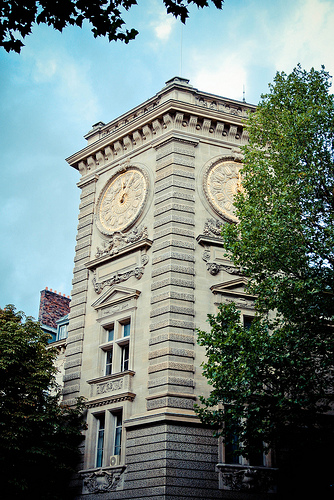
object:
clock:
[94, 157, 154, 237]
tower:
[124, 72, 221, 500]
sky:
[276, 4, 333, 63]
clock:
[198, 156, 276, 228]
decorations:
[89, 228, 150, 263]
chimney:
[40, 284, 72, 324]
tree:
[208, 55, 334, 490]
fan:
[109, 454, 120, 466]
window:
[110, 408, 122, 462]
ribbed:
[167, 205, 195, 416]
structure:
[136, 137, 206, 464]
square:
[56, 314, 70, 340]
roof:
[66, 85, 174, 161]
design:
[79, 467, 122, 496]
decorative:
[94, 231, 149, 253]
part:
[145, 332, 198, 410]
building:
[130, 404, 205, 500]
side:
[116, 344, 160, 420]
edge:
[158, 433, 173, 500]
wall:
[169, 331, 215, 500]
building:
[215, 98, 296, 486]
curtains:
[95, 417, 103, 469]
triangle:
[91, 283, 141, 310]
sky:
[0, 20, 79, 79]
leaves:
[200, 397, 228, 431]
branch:
[211, 320, 254, 362]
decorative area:
[84, 233, 152, 293]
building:
[64, 118, 133, 497]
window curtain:
[115, 414, 122, 456]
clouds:
[182, 35, 252, 79]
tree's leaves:
[0, 0, 110, 55]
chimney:
[35, 286, 70, 329]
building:
[34, 323, 67, 426]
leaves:
[194, 372, 246, 417]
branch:
[256, 318, 331, 354]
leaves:
[32, 382, 53, 404]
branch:
[1, 330, 35, 353]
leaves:
[27, 320, 34, 329]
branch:
[0, 355, 26, 376]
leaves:
[220, 307, 238, 328]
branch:
[304, 390, 334, 419]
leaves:
[60, 411, 73, 431]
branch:
[0, 410, 18, 453]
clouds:
[30, 50, 101, 95]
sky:
[2, 203, 61, 284]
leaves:
[303, 302, 317, 329]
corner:
[145, 69, 196, 499]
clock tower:
[59, 74, 313, 498]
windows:
[96, 312, 133, 377]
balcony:
[85, 369, 135, 404]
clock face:
[195, 143, 271, 237]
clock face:
[93, 157, 155, 240]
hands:
[119, 171, 135, 201]